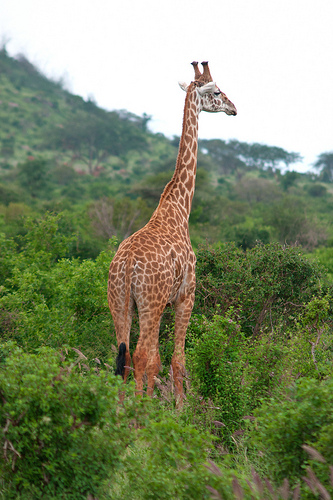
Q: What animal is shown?
A: A giraffe.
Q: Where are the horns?
A: On the giraffes head.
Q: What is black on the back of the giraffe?
A: His tail.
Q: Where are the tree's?
A: On the hill.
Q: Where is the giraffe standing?
A: In short bushes.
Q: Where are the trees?
A: On the hill.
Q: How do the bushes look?
A: Very green.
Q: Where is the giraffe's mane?
A: Along the back of the neck.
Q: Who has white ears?
A: The giraffe.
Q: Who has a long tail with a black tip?
A: The giraffe.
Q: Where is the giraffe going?
A: To feed on the trees.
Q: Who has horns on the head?
A: The giraffe.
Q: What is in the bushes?
A: Giraffe.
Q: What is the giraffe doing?
A: Walking.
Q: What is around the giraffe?
A: Bushes.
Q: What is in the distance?
A: Trees.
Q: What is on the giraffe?
A: Spots.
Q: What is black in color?
A: The tail.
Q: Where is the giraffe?
A: In the wild.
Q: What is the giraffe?
A: Brown and white.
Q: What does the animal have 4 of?
A: Legs.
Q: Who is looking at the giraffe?
A: The photographer.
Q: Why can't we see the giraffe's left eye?
A: Because the giraffe is looking right.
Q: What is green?
A: The vegetation.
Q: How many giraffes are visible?
A: One.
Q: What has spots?
A: The giraffe.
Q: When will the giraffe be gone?
A: When it decides to move on.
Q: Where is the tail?
A: On the back of the giraffe.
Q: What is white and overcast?
A: The sky.